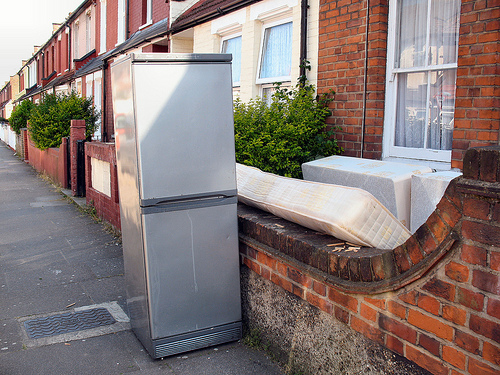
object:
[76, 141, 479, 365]
wall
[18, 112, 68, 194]
enclosure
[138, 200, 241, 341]
door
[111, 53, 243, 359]
appliance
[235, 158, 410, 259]
mattress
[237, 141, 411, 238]
box springs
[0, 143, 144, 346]
sidewalk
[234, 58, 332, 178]
green plants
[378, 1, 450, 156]
windows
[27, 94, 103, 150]
planter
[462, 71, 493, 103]
bricks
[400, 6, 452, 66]
curtains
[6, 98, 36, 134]
bush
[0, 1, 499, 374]
building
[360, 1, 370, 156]
pipe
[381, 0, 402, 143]
frame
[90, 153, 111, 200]
grate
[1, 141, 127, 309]
pavement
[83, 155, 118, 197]
plate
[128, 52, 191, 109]
corner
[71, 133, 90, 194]
gate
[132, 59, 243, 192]
door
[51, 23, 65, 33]
chimney